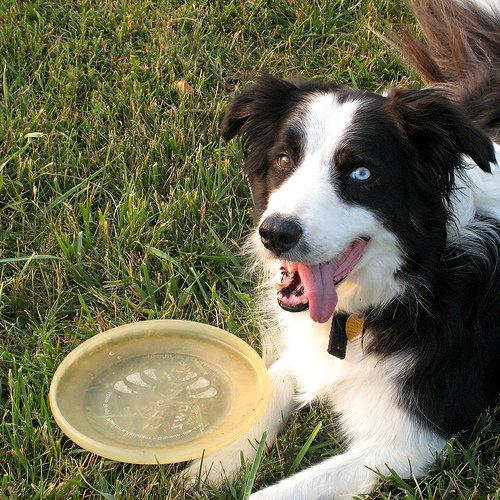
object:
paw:
[169, 448, 228, 496]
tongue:
[296, 255, 338, 325]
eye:
[271, 150, 297, 172]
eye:
[346, 162, 373, 185]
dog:
[164, 0, 500, 497]